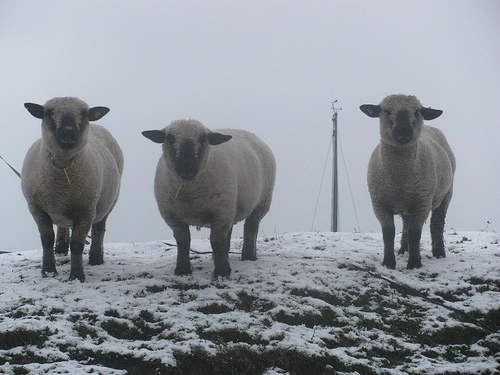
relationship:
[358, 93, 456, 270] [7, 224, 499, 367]
animal standing on snow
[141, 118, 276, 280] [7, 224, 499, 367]
animal standing on snow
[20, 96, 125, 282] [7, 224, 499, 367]
animal standing on snow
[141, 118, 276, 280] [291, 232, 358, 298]
animal standing on snow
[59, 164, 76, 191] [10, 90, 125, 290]
yellow tag on lamb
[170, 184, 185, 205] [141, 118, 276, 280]
yellow tag on animal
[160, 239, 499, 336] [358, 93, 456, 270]
cable next to animal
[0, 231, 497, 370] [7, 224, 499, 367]
grass on snow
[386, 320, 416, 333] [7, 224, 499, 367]
grass on snow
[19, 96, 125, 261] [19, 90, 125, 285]
fur on animal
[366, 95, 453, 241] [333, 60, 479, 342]
fur on animal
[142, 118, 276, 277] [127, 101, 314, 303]
fur on animal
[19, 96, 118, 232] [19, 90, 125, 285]
fur on animal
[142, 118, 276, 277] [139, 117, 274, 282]
fur on animal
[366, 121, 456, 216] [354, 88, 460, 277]
fur on animal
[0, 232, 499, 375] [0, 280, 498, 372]
snow covering grass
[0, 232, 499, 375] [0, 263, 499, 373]
snow on ground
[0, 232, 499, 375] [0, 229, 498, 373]
snow on ground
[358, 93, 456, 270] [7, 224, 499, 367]
animal on snow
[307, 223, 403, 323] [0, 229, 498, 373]
snowy plants on ground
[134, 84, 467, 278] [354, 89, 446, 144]
sheep has raised head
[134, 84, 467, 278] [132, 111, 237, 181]
sheep has lowered head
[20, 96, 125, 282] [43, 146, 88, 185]
animal wearing collar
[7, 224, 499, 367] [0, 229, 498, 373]
snow on ground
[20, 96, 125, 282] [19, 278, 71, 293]
animal standing on snow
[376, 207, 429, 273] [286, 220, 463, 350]
legs in snow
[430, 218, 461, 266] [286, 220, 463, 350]
leg in snow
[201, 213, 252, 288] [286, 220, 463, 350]
leg in snow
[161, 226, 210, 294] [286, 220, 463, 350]
leg in snow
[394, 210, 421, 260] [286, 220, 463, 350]
leg in snow